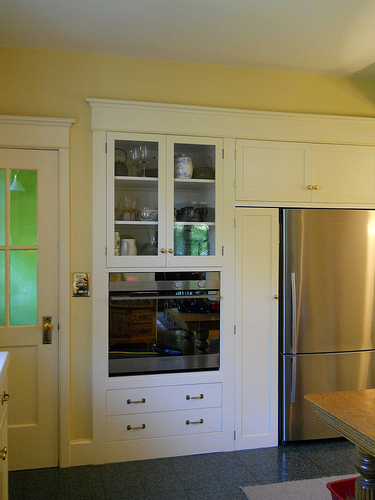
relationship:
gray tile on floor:
[15, 436, 365, 499] [6, 438, 357, 498]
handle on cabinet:
[307, 183, 318, 189] [235, 137, 372, 207]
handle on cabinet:
[157, 247, 166, 256] [102, 129, 168, 269]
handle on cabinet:
[1, 451, 4, 459] [1, 349, 9, 498]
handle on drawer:
[181, 390, 206, 401] [105, 382, 223, 417]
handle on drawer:
[127, 398, 146, 405] [105, 382, 223, 417]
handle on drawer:
[185, 416, 206, 424] [105, 405, 226, 440]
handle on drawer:
[125, 419, 146, 429] [105, 405, 226, 440]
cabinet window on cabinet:
[112, 137, 159, 175] [87, 97, 237, 463]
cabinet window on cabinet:
[172, 142, 217, 181] [87, 97, 237, 463]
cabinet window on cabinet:
[109, 177, 160, 222] [87, 97, 237, 463]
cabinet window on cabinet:
[174, 180, 216, 223] [87, 97, 237, 463]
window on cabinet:
[173, 140, 213, 255] [87, 97, 237, 463]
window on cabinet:
[112, 136, 158, 258] [87, 97, 237, 463]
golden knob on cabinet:
[158, 243, 168, 255] [90, 96, 231, 266]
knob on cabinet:
[166, 246, 176, 254] [90, 96, 231, 266]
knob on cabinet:
[312, 185, 320, 190] [87, 97, 237, 463]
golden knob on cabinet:
[160, 248, 165, 253] [87, 97, 237, 463]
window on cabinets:
[112, 136, 158, 258] [80, 94, 374, 463]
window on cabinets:
[173, 140, 213, 255] [80, 94, 374, 463]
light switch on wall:
[71, 270, 89, 298] [2, 46, 371, 467]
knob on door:
[36, 315, 58, 346] [0, 141, 59, 475]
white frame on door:
[15, 106, 80, 353] [0, 141, 59, 475]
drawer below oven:
[105, 382, 223, 417] [108, 270, 220, 376]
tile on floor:
[133, 458, 171, 471] [7, 432, 364, 498]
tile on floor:
[176, 472, 222, 492] [7, 432, 364, 498]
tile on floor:
[245, 460, 288, 483] [7, 432, 364, 498]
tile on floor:
[310, 450, 355, 475] [7, 432, 364, 498]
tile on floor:
[205, 450, 245, 471] [7, 432, 364, 498]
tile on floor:
[214, 461, 255, 484] [158, 455, 228, 497]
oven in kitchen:
[108, 270, 220, 376] [51, 66, 372, 302]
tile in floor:
[232, 441, 310, 482] [79, 445, 317, 498]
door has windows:
[3, 112, 80, 473] [5, 122, 66, 467]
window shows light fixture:
[10, 170, 37, 246] [7, 171, 27, 191]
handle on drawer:
[127, 398, 146, 405] [105, 382, 222, 416]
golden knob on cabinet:
[160, 248, 165, 253] [101, 134, 229, 282]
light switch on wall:
[71, 270, 89, 298] [28, 89, 329, 438]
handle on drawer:
[124, 396, 147, 403] [85, 380, 237, 452]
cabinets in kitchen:
[85, 96, 375, 465] [2, 1, 373, 496]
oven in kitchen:
[109, 270, 216, 369] [71, 193, 373, 494]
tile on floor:
[213, 465, 259, 493] [7, 432, 364, 498]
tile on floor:
[245, 459, 295, 486] [6, 438, 357, 498]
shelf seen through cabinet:
[112, 169, 216, 187] [82, 85, 375, 463]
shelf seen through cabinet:
[112, 215, 217, 230] [82, 85, 375, 463]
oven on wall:
[108, 270, 220, 376] [69, 162, 102, 276]